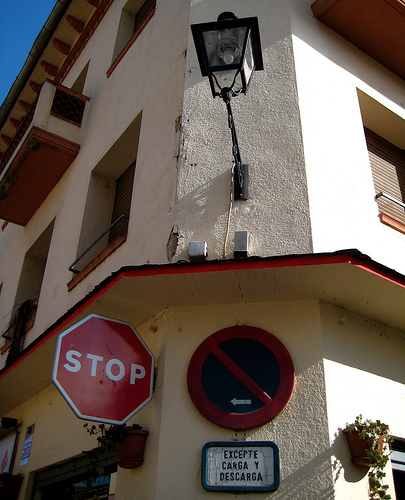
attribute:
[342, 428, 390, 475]
flower pot — brown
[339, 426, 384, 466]
pot — brown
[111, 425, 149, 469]
pot — brown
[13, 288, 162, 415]
sign — red, white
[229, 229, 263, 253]
power box — silver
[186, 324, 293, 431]
sign — red, black , white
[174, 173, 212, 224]
wall — broken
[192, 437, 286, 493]
sign — blue and white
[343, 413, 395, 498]
vine — green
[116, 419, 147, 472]
pot — clay, brown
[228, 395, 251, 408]
arrow — white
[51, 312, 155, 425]
sign — octagon, octagonal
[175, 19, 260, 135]
sign — red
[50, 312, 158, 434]
traffic sign — red, white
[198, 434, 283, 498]
sign — framed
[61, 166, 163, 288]
balcony — small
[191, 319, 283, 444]
sign — red, black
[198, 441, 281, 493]
sign — white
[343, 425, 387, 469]
flower pot — clay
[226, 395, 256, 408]
arrow — white